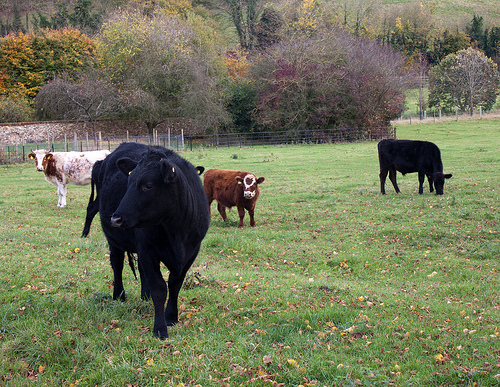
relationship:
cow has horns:
[26, 146, 110, 209] [29, 148, 54, 156]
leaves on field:
[2, 186, 497, 386] [0, 119, 500, 387]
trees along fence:
[0, 14, 406, 142] [3, 125, 187, 162]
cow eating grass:
[373, 136, 454, 193] [3, 122, 500, 384]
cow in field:
[376, 137, 453, 195] [5, 121, 500, 385]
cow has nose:
[81, 140, 211, 339] [111, 216, 125, 228]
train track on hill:
[0, 115, 79, 127] [0, 116, 82, 152]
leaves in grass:
[2, 186, 497, 386] [3, 122, 500, 384]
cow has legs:
[81, 140, 211, 339] [135, 252, 190, 338]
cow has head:
[81, 140, 211, 339] [107, 150, 180, 232]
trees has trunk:
[390, 14, 500, 116] [414, 61, 429, 116]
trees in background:
[0, 14, 406, 142] [3, 0, 498, 145]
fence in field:
[3, 125, 187, 162] [5, 121, 500, 385]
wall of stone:
[3, 116, 83, 148] [0, 122, 71, 145]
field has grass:
[5, 121, 500, 385] [3, 122, 500, 384]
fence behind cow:
[3, 125, 187, 162] [376, 137, 453, 195]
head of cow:
[235, 170, 264, 202] [200, 169, 263, 227]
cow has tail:
[81, 140, 211, 339] [80, 161, 104, 241]